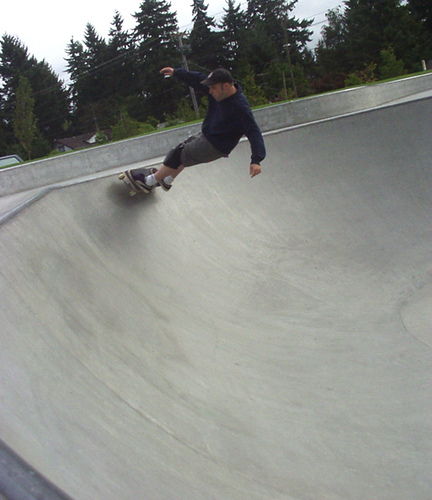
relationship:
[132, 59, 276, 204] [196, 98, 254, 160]
man wearing sweatshirt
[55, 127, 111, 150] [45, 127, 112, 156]
brown roof of a house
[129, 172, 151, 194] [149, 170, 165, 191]
shoe has sole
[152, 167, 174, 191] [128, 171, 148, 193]
shoe has sole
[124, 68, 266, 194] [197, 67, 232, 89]
man has hat